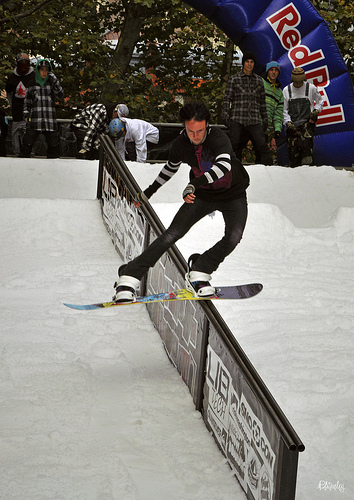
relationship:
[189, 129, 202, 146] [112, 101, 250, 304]
nose of guy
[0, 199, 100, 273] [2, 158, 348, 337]
snow on ground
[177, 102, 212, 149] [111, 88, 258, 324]
head on person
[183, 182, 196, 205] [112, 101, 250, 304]
hand of guy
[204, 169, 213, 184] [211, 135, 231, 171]
stripe on cloth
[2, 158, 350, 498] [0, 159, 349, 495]
snow on ground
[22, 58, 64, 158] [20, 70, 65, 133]
guy wears jacket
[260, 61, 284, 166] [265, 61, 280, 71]
guy wearing blue bonnet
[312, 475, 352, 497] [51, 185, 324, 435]
name of studio who took photo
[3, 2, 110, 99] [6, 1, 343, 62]
trees in background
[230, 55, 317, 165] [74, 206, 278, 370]
men getting ready for their turn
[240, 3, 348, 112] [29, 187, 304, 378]
red bull a sponsor of event